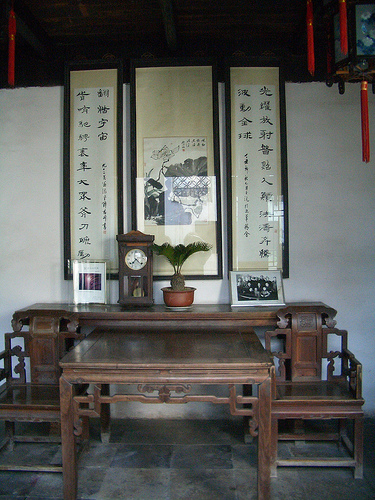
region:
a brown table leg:
[253, 379, 274, 497]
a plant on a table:
[158, 237, 202, 308]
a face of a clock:
[122, 246, 148, 270]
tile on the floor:
[122, 435, 199, 486]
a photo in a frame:
[225, 270, 292, 305]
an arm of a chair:
[325, 340, 373, 412]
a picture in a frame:
[69, 253, 109, 306]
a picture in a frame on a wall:
[128, 127, 231, 232]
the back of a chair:
[277, 309, 343, 383]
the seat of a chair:
[285, 382, 347, 410]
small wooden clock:
[115, 228, 156, 306]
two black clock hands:
[128, 254, 144, 268]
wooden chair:
[259, 300, 367, 480]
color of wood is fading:
[271, 451, 362, 485]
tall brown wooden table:
[58, 320, 282, 498]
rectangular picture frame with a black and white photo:
[225, 266, 285, 310]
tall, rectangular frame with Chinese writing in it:
[230, 69, 290, 277]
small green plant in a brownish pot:
[155, 234, 208, 307]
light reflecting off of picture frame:
[71, 261, 107, 305]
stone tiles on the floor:
[3, 419, 373, 499]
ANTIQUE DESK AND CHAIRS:
[1, 280, 358, 491]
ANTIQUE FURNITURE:
[9, 278, 372, 486]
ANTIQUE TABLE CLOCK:
[103, 220, 163, 311]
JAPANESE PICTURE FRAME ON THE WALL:
[39, 50, 319, 275]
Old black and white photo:
[217, 257, 297, 312]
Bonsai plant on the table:
[150, 228, 210, 315]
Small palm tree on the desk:
[145, 227, 233, 319]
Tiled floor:
[62, 416, 297, 493]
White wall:
[8, 73, 107, 237]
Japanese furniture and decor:
[7, 16, 371, 452]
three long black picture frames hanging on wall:
[43, 56, 302, 284]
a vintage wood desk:
[2, 283, 371, 492]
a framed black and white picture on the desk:
[225, 264, 294, 307]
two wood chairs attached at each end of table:
[0, 304, 373, 471]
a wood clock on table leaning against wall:
[114, 218, 158, 315]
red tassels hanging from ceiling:
[298, 4, 369, 78]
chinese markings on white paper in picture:
[69, 77, 133, 277]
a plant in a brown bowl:
[149, 233, 212, 313]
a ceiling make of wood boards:
[6, 4, 352, 91]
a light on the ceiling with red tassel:
[313, 6, 374, 156]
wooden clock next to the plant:
[109, 225, 211, 312]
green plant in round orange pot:
[147, 236, 209, 319]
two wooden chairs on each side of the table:
[6, 286, 369, 495]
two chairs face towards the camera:
[0, 293, 368, 493]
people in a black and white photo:
[227, 261, 296, 312]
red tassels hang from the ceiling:
[2, 3, 369, 168]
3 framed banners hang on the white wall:
[42, 57, 306, 285]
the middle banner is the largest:
[53, 46, 298, 281]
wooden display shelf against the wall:
[12, 287, 349, 383]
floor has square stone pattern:
[1, 417, 372, 497]